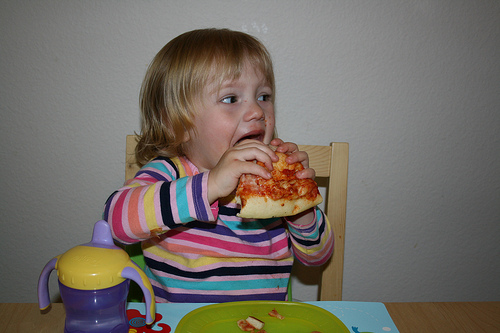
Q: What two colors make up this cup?
A: Purple and yellow.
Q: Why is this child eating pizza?
A: It's hungry.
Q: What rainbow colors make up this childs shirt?
A: Red blue orange yellow pink black.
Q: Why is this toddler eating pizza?
A: It's hungry.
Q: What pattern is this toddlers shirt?
A: Stripes.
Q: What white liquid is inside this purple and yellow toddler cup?
A: Milk.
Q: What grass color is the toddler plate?
A: Green.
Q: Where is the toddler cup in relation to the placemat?
A: To the left.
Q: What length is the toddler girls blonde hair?
A: Shoulder length.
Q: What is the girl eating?
A: Pizza.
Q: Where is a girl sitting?
A: On a chair.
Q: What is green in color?
A: Plate.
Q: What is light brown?
A: The chair.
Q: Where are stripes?
A: On girl's shirt.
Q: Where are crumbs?
A: On the plate.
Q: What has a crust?
A: Pizza.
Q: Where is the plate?
A: On a placemat.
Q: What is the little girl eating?
A: Pizza.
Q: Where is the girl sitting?
A: By table.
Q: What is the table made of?
A: Wood.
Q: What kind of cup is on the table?
A: Sippy cup.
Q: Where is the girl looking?
A: To the right.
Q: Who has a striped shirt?
A: Little girl.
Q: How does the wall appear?
A: Bare.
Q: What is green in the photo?
A: Plate.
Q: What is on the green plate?
A: Crumbs.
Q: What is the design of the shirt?
A: Striped.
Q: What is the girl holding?
A: Pizza.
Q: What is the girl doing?
A: Eating pizza.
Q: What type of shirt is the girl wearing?
A: Striped long sleeved shirt.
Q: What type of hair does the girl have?
A: Long blonde hair.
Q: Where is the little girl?
A: At the table.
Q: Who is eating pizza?
A: A little girl.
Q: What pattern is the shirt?
A: Stripes.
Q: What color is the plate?
A: Green.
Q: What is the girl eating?
A: Pizza.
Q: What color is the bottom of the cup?
A: Purple.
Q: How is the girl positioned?
A: She's sitting down.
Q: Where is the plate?
A: On a placemat.